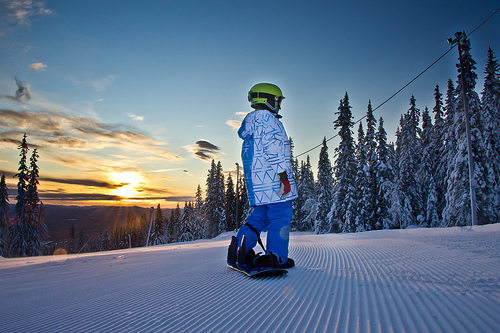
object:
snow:
[0, 221, 500, 332]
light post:
[450, 31, 478, 225]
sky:
[0, 0, 500, 210]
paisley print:
[438, 30, 499, 228]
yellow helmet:
[248, 82, 287, 115]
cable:
[291, 9, 500, 159]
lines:
[0, 257, 225, 328]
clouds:
[224, 119, 241, 130]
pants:
[235, 200, 294, 267]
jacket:
[237, 109, 299, 206]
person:
[230, 82, 301, 269]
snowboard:
[226, 263, 288, 278]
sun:
[104, 171, 148, 199]